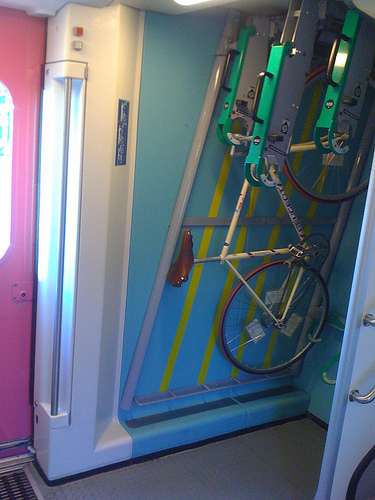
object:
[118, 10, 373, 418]
wall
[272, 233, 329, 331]
chain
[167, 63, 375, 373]
bicycle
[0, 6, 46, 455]
door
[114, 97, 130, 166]
sign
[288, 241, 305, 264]
pedal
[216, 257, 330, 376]
wheel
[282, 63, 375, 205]
tire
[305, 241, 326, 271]
chainring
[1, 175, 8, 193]
window part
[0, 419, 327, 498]
floor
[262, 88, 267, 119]
metal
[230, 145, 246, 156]
bars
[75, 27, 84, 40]
red light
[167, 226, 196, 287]
seat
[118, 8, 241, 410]
rack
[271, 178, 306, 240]
brand name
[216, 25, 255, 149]
bike rack